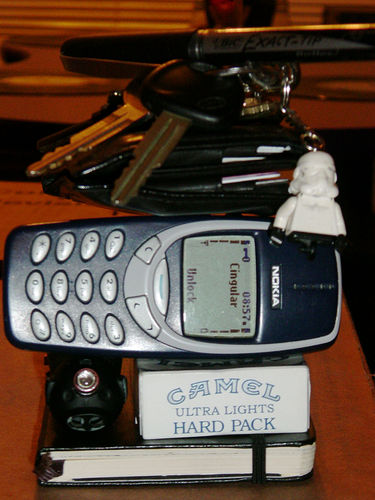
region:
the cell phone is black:
[10, 216, 351, 360]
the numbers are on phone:
[28, 230, 126, 345]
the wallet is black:
[65, 120, 305, 212]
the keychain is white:
[272, 133, 350, 242]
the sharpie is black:
[62, 18, 370, 85]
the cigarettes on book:
[119, 358, 308, 475]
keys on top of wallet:
[69, 76, 304, 211]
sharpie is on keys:
[60, 25, 371, 119]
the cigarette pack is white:
[130, 361, 313, 445]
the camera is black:
[47, 345, 132, 438]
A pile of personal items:
[44, 51, 347, 485]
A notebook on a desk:
[20, 426, 342, 496]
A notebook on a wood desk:
[20, 432, 352, 491]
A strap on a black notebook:
[197, 418, 315, 484]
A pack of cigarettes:
[127, 362, 331, 442]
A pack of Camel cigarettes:
[124, 358, 320, 438]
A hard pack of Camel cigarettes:
[126, 352, 323, 442]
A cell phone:
[10, 207, 346, 374]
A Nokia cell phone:
[12, 201, 360, 369]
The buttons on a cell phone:
[23, 229, 140, 347]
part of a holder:
[265, 192, 312, 227]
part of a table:
[337, 429, 369, 482]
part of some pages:
[159, 449, 178, 467]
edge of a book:
[134, 437, 161, 455]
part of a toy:
[73, 381, 118, 425]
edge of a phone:
[147, 335, 188, 355]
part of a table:
[318, 399, 353, 448]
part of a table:
[334, 413, 370, 457]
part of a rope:
[253, 455, 274, 479]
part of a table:
[335, 369, 364, 416]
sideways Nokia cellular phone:
[3, 216, 346, 354]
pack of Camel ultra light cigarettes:
[137, 360, 312, 435]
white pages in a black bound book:
[39, 431, 319, 489]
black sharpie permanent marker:
[62, 27, 374, 66]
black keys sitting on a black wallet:
[37, 65, 372, 224]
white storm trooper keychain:
[278, 148, 353, 259]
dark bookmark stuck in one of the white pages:
[35, 456, 67, 484]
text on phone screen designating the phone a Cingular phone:
[226, 259, 241, 315]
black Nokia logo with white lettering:
[268, 263, 288, 312]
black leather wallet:
[36, 139, 321, 218]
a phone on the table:
[4, 214, 353, 355]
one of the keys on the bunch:
[106, 104, 192, 211]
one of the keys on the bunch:
[24, 96, 146, 177]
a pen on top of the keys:
[172, 23, 373, 59]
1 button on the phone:
[102, 227, 125, 258]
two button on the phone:
[98, 270, 116, 303]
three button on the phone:
[104, 311, 124, 345]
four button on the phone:
[78, 230, 100, 266]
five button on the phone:
[74, 268, 94, 304]